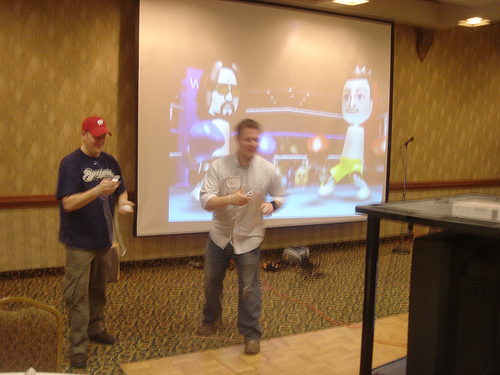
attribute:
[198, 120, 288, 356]
man — grown., playing., smiling.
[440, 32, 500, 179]
wallpaper — patterned.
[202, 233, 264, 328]
jeans. — blue.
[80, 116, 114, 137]
hat. — red.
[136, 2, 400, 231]
screen — big., huge., projection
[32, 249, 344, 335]
floor — carpeted.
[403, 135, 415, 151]
microphone — black., available.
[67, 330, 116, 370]
shoes — brown.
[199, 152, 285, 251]
shirt — white.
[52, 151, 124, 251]
tshirt — blue.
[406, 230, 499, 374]
tv — here.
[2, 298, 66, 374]
chair — left., called.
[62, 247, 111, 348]
pants — brown.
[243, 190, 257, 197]
controller — wii.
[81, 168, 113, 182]
writing — white.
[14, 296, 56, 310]
frame — gold.